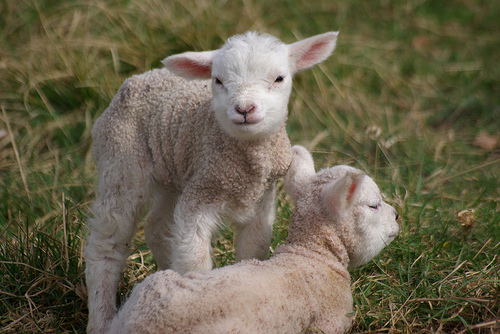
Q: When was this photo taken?
A: Outside, during the daytime.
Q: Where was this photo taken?
A: In a grassy area.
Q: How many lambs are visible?
A: Two.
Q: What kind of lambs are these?
A: Baby lambs.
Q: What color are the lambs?
A: White.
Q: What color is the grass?
A: Green.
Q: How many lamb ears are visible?
A: Four.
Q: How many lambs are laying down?
A: One.